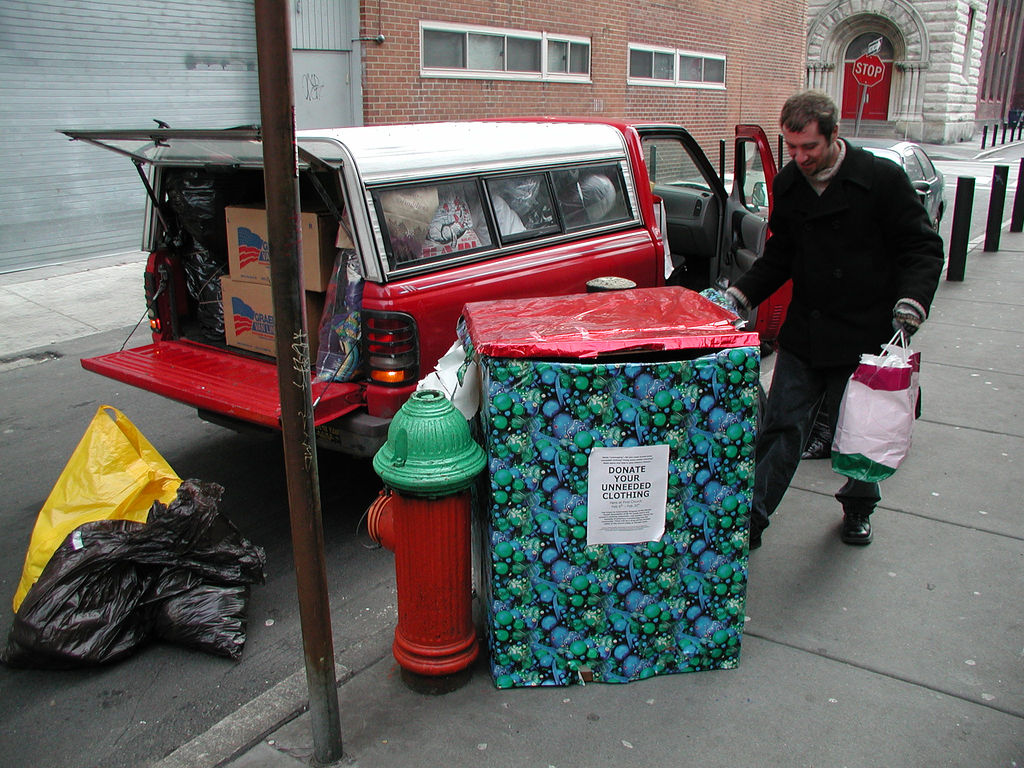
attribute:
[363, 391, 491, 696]
hydrant — red, green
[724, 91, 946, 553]
man — walking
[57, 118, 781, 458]
truck — red, white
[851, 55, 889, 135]
sign — red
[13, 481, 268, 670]
bags — black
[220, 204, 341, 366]
boxes — collection, wrapped, cardboard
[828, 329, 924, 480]
bag — white, red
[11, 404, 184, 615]
bag — yellow, large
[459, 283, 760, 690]
box — colorful, large, blue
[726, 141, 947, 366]
coat — black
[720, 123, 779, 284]
door — open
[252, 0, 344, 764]
pole — brown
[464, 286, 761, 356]
top of box — red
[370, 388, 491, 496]
hydrant top — green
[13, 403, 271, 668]
bags — colorful